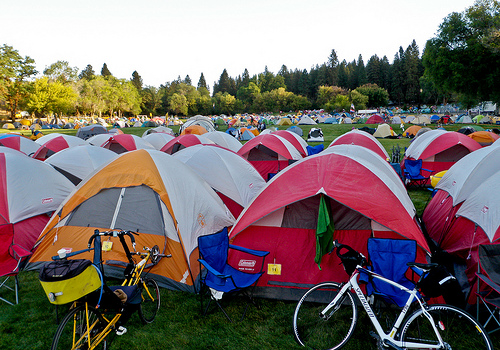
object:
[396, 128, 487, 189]
tents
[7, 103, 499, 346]
field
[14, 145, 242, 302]
tent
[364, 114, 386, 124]
tents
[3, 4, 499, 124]
distance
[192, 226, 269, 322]
folding chair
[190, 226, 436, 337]
two folding chairs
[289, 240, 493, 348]
bicycle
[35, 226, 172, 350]
reclining bicycle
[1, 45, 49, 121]
trees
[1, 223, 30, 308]
folding chair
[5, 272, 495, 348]
grass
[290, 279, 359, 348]
wheel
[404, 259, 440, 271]
seat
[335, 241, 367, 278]
handlebars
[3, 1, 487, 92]
sky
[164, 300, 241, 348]
patch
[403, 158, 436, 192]
chair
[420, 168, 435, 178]
arm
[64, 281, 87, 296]
yellow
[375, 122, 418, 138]
two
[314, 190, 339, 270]
towel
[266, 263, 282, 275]
tag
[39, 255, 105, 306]
storage container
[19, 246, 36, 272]
black trim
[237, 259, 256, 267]
decal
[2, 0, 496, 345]
park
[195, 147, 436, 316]
tent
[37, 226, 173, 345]
bicycles